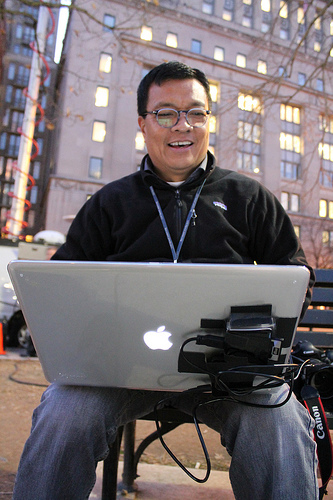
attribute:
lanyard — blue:
[143, 183, 212, 261]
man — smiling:
[13, 63, 320, 500]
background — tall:
[2, 1, 331, 268]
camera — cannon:
[282, 341, 332, 499]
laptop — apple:
[9, 260, 313, 391]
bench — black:
[302, 265, 331, 374]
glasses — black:
[145, 104, 208, 129]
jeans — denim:
[16, 386, 331, 499]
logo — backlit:
[140, 324, 173, 352]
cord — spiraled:
[5, 6, 60, 242]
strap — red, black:
[301, 393, 333, 479]